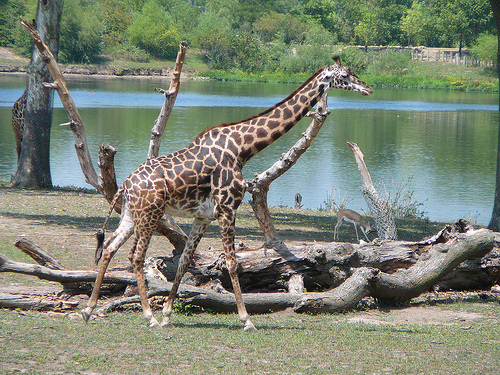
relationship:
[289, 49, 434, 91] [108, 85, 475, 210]
flowers on side of lake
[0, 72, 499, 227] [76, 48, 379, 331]
water next to giraffe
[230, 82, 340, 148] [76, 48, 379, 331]
neck of giraffe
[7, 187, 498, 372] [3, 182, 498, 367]
grass on ground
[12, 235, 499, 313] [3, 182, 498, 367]
log on ground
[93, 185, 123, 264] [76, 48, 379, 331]
giraffe`s tail of giraffe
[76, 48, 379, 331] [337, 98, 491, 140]
giraffe next water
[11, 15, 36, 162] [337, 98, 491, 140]
giraffe next water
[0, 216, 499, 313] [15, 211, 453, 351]
log on ground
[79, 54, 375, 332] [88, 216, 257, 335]
giraffe has legs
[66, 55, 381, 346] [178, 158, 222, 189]
animal has spots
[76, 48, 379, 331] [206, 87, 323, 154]
giraffe has neck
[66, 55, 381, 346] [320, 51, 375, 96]
animal has head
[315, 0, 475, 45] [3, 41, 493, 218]
trees around lake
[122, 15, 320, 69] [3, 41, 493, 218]
shrubs around lake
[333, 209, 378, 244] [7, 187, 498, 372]
animal eating grass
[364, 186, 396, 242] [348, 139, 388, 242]
fencing around tree limb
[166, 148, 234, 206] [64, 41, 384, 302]
spots on giraffe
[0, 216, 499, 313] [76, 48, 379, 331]
log next to giraffe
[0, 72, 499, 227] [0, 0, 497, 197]
water in background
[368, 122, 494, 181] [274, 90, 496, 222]
reflection in water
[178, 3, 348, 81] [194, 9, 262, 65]
trees in distance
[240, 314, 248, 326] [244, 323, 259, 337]
part of a hoof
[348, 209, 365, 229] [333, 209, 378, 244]
part of a animal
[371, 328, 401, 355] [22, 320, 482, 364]
part of a ground